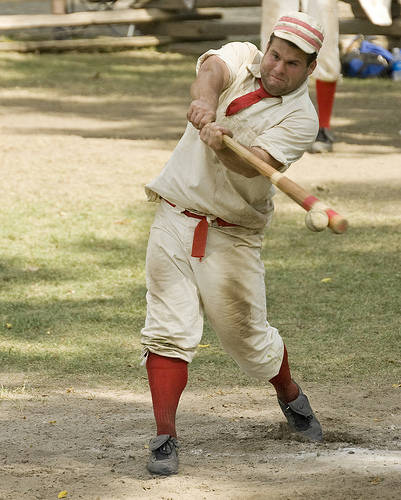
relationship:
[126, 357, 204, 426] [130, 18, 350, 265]
sock on man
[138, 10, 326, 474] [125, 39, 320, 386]
baseball player wearing uniform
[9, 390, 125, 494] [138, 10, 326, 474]
dirt around baseball player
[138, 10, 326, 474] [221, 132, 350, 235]
baseball player holding ball bat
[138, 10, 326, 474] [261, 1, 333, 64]
baseball player wearing hat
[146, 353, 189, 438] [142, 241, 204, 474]
sock on leg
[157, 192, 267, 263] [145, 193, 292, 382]
belt in pants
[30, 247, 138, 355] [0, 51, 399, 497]
shadow on ground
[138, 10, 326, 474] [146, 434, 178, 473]
baseball player wearing shoe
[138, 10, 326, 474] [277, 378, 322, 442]
baseball player wearing shoe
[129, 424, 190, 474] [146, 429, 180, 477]
cleat is on foot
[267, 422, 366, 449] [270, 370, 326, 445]
hole is next to foot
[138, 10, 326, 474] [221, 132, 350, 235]
baseball player is holding ball bat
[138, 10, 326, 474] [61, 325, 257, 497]
baseball player wearing socks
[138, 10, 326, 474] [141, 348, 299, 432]
baseball player wearing socks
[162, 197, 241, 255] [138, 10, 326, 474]
belt on baseball player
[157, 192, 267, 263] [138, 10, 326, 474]
belt on baseball player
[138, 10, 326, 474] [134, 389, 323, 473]
baseball player wearing shoes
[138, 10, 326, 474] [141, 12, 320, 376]
baseball player wearing baseball uniform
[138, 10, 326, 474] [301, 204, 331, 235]
baseball player hitting ball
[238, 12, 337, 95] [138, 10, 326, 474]
head on baseball player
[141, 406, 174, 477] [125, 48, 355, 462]
foot on man